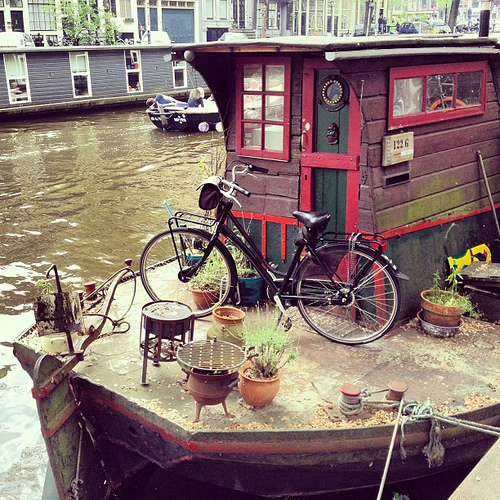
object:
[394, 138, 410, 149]
1226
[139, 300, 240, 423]
stoves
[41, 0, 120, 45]
greenleaves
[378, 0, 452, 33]
greenleaves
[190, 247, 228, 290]
greenleaves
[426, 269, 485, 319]
greenleaves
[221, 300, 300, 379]
greenleaves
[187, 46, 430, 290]
structure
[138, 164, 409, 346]
bicycle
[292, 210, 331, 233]
seat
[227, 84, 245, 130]
wall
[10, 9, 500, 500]
boat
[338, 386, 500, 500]
rope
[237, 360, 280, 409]
pot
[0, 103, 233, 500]
water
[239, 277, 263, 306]
bucket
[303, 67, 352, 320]
door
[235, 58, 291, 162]
window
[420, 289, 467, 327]
pot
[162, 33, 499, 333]
building